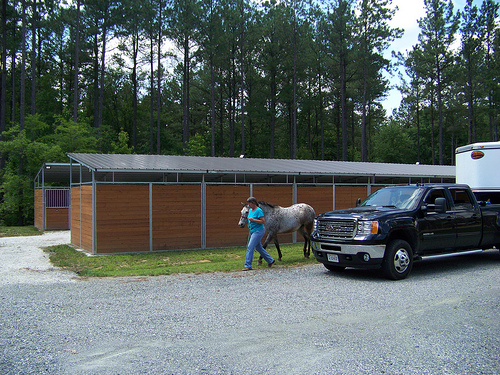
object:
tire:
[384, 238, 415, 281]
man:
[241, 198, 276, 272]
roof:
[64, 150, 457, 180]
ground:
[0, 224, 500, 375]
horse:
[237, 196, 316, 266]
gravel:
[0, 229, 499, 374]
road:
[0, 226, 500, 375]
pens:
[66, 152, 457, 256]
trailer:
[453, 140, 500, 193]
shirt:
[247, 207, 265, 234]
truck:
[306, 181, 500, 282]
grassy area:
[38, 241, 320, 278]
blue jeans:
[242, 228, 274, 269]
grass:
[36, 242, 325, 279]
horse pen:
[30, 161, 70, 231]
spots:
[295, 217, 298, 219]